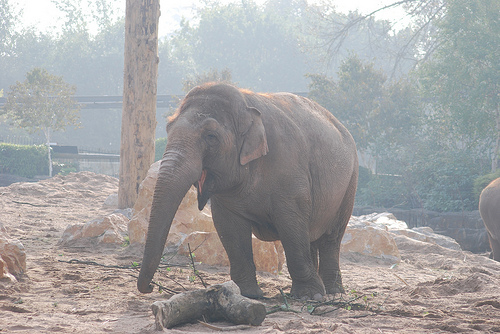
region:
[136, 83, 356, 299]
the elephant in the enclosure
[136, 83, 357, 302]
the animal in the enclosure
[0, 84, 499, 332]
the enclosed area for the elephant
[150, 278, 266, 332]
the log on the ground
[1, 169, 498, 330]
the dirt on the ground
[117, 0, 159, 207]
the wood pole near the elephant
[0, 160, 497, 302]
the large rocks in the enclosure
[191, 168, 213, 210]
the mouth of the elephant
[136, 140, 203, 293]
the trunk on the elephant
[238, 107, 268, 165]
the ear on the elephant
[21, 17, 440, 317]
a picture of a happy elephant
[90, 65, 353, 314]
the elephant is smiling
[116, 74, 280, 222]
this elephant has a whimsical look on its face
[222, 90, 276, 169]
the elephant's ear is small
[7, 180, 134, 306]
the dirt on the ground is rough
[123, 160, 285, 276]
a large boulder behind the elephant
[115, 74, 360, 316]
the elephant is colored gray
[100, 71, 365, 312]
this elephant is young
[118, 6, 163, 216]
a tree trunk beside the elephant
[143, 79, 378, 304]
the elephant is grey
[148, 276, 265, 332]
v shaped log is on the ground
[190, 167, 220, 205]
the mouth is open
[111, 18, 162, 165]
the tree barkis brown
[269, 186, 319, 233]
wrinkles ae on the elephant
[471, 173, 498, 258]
the elephant is halfly seen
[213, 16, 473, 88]
trees are in the background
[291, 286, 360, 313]
twigs are on the sand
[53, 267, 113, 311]
foot prints are on the sand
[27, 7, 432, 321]
an elephant in the area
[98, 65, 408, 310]
the elephant looks happy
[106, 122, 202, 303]
the elephant has a long trunk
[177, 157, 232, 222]
this elephant is smiling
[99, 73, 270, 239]
the elephant looks young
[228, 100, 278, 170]
this elephant has small ears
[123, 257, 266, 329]
a wooden log beneath the elephant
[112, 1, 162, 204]
a tree trunk near the elephant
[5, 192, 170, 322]
the elephant is standing on uneven ground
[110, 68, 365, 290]
this is a gray colored elephant